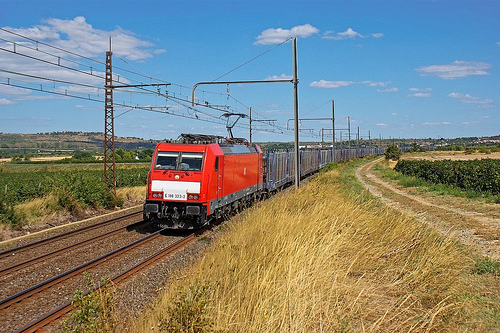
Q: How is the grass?
A: Dry.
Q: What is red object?
A: Train.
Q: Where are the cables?
A: Above train.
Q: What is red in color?
A: The front of the train.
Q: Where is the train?
A: The train is along two long railway tracks.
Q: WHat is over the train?
A: Small electrical wires.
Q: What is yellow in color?
A: Beautiful, dry grass.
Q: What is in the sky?
A: There are small white clouds.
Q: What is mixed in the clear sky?
A: There are white clouds.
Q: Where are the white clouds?
A: The white clouds are in the clear sky.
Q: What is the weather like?
A: Clear.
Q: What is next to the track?
A: A grassy field.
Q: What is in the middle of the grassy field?
A: Train tracks.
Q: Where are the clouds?
A: In the sky.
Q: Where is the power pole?
A: Near the tracks.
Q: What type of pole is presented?
A: A power pole.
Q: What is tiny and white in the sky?
A: Clouds.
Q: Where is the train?
A: On the tracks.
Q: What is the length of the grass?
A: Long.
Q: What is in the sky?
A: White clouds.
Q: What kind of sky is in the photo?
A: Clear.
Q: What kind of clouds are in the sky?
A: White.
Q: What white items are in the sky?
A: Clouds.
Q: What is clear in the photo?
A: Sky.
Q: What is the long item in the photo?
A: Train.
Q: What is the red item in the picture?
A: Train engine.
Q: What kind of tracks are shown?
A: Railroad.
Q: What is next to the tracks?
A: Tall grass.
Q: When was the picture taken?
A: During the day.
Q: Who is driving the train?
A: The conductor.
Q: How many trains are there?
A: One.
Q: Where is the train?
A: On the tracks.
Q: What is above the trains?
A: Wires.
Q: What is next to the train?
A: Grass.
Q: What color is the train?
A: Red.